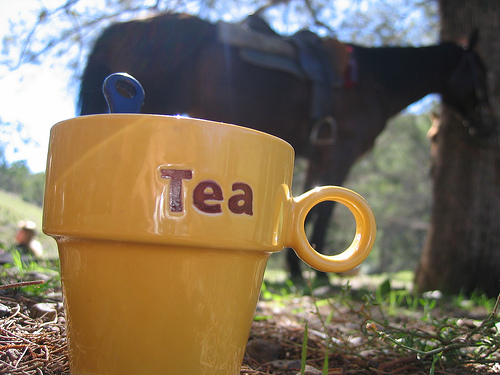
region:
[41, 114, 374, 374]
a small brown tea pot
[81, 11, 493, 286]
a dark brown horse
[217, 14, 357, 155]
a leather saddle on the horse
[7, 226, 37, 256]
a guy sitting in the grass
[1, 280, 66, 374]
a bundle of sticks on the ground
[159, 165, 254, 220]
red letters on the pot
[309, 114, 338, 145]
a silver stirrup on the saddle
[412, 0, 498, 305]
a tall brown tree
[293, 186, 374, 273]
a brown tea handle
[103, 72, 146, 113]
a blue handle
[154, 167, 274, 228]
Tea is written in red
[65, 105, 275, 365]
the mug is yellow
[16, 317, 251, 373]
the mug is sitting on the ground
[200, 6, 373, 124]
the horse is wearing a saddle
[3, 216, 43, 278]
person in the grass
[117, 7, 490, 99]
horse standing under a tree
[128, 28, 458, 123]
the horse is brown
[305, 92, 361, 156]
the stirup for the saddle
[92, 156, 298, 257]
Tea is written on a mug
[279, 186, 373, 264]
the handle is round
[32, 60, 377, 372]
Gold tea tea cup sitting on ground.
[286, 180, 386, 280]
Round handle on gold tea cup.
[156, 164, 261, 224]
Tea written in brown on tea cup.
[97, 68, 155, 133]
Handle of spoon sticking out of tea cup.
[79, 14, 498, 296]
Horse standing behind tea cup.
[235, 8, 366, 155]
Saddle on a horse.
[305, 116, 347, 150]
Stirrup attached to saddle.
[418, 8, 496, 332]
Trunk of tree next to horse.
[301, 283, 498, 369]
Weeds growing on ground near tea cup.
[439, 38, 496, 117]
Bridle around horse's head.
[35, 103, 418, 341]
A yellow mug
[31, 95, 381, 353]
A yellow mug with red letters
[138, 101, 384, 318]
The handle of a yellow mug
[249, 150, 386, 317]
a round handle on a mug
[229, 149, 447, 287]
a handle pointing to the right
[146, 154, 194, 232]
a red letter "T"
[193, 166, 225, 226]
a red letter "e"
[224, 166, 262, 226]
a red letter "a"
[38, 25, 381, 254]
A horse behind a mug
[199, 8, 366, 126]
A saddle on a horse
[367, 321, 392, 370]
part of a plant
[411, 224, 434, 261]
edge of a tree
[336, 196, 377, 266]
part of a handle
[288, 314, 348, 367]
part of a ground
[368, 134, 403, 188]
part of a tree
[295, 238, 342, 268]
edge of a handle